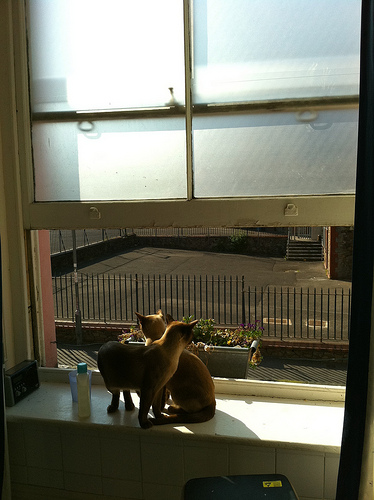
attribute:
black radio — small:
[8, 352, 53, 390]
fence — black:
[45, 225, 352, 344]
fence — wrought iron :
[115, 261, 330, 318]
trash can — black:
[173, 467, 304, 499]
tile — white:
[274, 449, 323, 498]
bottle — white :
[76, 370, 90, 418]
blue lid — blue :
[77, 360, 87, 373]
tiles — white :
[4, 413, 337, 498]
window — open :
[24, 13, 355, 388]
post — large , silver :
[69, 228, 85, 346]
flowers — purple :
[166, 318, 254, 352]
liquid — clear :
[66, 367, 91, 398]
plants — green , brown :
[190, 323, 250, 352]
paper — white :
[29, 1, 177, 104]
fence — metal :
[48, 275, 349, 334]